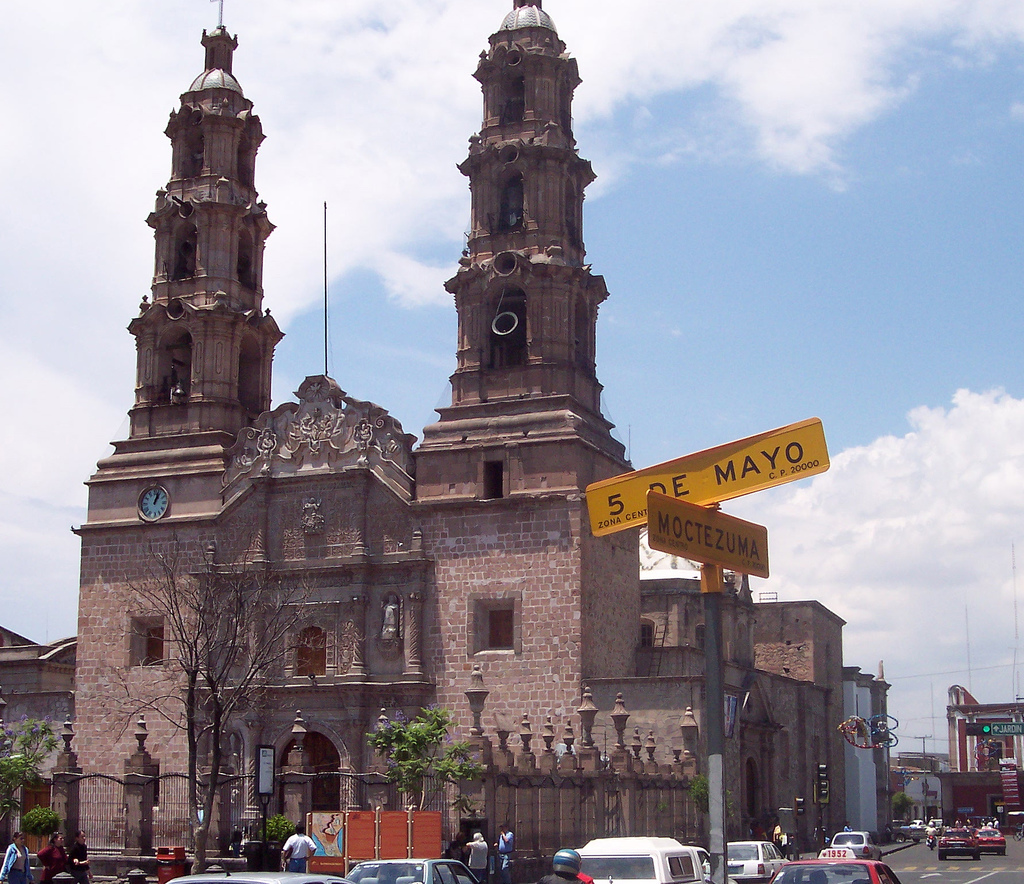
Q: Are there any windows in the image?
A: Yes, there is a window.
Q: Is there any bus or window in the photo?
A: Yes, there is a window.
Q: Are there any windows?
A: Yes, there is a window.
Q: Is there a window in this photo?
A: Yes, there is a window.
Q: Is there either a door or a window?
A: Yes, there is a window.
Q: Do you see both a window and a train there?
A: No, there is a window but no trains.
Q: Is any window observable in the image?
A: Yes, there is a window.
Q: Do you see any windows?
A: Yes, there is a window.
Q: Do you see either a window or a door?
A: Yes, there is a window.